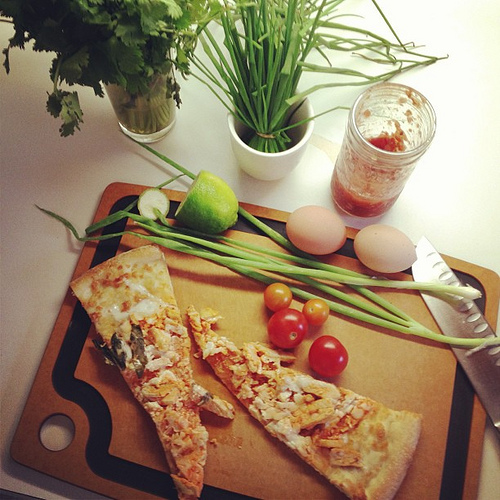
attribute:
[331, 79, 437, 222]
jar — mostly empty, glass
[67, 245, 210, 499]
pizza — sliced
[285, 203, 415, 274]
eggs — brown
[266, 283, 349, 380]
tomatoes — round, red, cherry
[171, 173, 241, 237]
lime — green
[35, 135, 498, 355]
green onions — fresh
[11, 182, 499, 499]
chopping board — wooden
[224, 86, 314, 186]
cup — white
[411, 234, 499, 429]
knife blade — silver, sharp, serrated steel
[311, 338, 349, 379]
tomato — bright red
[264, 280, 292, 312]
tomato — orange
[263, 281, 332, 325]
tomatoes — orange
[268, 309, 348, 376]
tomatoes — red